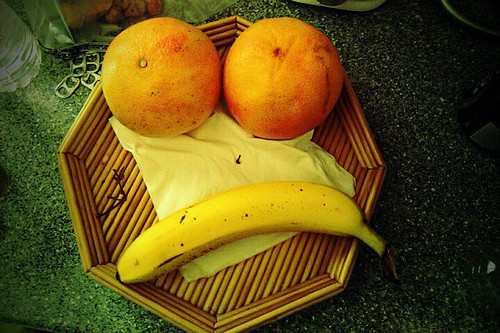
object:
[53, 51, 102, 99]
pile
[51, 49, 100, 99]
tabs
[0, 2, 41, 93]
bottle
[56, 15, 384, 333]
basket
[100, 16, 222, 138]
fruit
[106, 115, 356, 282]
napkin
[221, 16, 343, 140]
fruit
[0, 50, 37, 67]
glass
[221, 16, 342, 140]
orange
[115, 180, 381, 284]
banana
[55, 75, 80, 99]
pull tab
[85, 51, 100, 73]
pull tab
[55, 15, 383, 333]
plate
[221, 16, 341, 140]
grapefruit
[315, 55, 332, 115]
bruise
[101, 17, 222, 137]
grapefruit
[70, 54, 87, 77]
pull tab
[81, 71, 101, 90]
pull tab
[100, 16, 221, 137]
orange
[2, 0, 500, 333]
counter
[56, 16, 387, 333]
frowning face